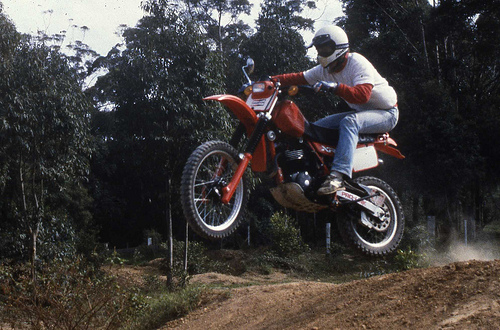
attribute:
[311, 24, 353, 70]
helmet — white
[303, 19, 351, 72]
helmet — white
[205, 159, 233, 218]
tire — bike's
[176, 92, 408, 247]
bike — red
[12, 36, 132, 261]
branch — of tree, with leaves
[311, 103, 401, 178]
jeans — blue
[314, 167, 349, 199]
foot — person's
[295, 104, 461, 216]
jeans — light blue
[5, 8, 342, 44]
sky — at daytime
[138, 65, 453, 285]
bike. — for dirt 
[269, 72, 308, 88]
sleeve — red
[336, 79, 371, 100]
sleeve — red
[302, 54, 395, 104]
shirt — white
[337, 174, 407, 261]
rear wheel — the rear 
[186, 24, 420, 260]
bike — red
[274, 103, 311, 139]
tank — for gas